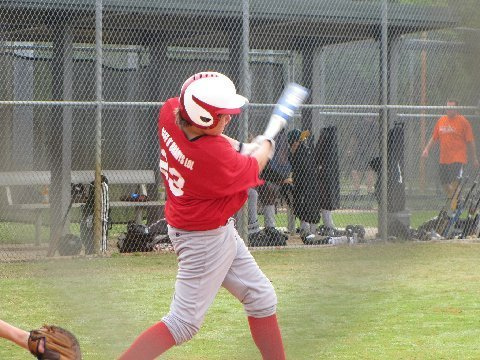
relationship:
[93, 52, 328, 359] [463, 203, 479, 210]
baseball player hitting ball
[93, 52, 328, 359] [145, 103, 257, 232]
baseball player in uniform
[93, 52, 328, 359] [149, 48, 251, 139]
baseball player in helmet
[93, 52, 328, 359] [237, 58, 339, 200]
baseball player in mid-swing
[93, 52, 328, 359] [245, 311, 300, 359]
baseball player in socks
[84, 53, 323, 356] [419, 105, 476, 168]
man in shirt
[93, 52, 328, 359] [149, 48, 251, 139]
baseball player wearing helmet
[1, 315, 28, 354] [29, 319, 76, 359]
person wearing mitt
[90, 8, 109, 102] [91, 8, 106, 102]
pole has rust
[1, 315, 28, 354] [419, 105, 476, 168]
person wearing shirt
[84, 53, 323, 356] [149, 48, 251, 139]
man wearing helmet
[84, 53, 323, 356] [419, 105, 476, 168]
man wearing shirt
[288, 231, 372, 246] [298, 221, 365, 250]
equipment of baseball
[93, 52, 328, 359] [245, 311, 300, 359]
baseball player wearing socks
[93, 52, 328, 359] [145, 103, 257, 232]
baseball player wearing uniform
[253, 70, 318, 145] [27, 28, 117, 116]
bat on fence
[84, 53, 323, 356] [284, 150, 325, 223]
man in jacket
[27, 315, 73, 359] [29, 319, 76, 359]
hand with glove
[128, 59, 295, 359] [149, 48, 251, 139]
batter wearing helmet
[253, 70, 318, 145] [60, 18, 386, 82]
bat in dugout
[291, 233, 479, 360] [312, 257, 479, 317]
field in field